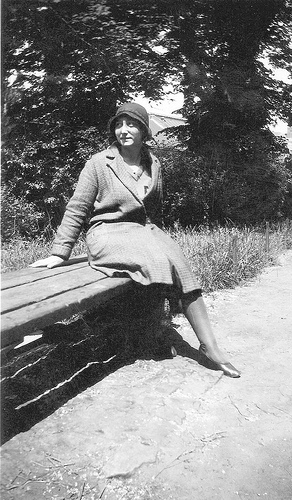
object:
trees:
[0, 1, 159, 236]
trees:
[164, 0, 292, 170]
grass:
[200, 236, 229, 266]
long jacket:
[51, 140, 202, 294]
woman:
[29, 102, 240, 380]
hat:
[110, 102, 152, 141]